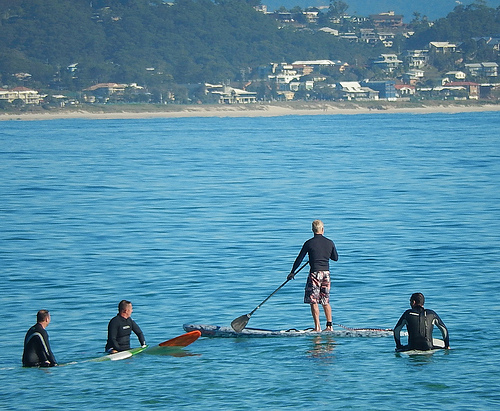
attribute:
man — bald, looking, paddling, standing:
[296, 204, 339, 327]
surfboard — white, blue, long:
[218, 325, 393, 341]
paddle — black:
[237, 254, 270, 334]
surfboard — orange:
[162, 327, 198, 353]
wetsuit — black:
[95, 322, 140, 350]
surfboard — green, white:
[85, 345, 159, 371]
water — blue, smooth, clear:
[18, 364, 229, 392]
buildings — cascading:
[186, 56, 483, 103]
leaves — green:
[130, 28, 175, 54]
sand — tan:
[172, 109, 282, 118]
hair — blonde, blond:
[306, 221, 334, 232]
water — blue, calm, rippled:
[35, 154, 498, 381]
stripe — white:
[257, 303, 263, 313]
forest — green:
[32, 18, 267, 64]